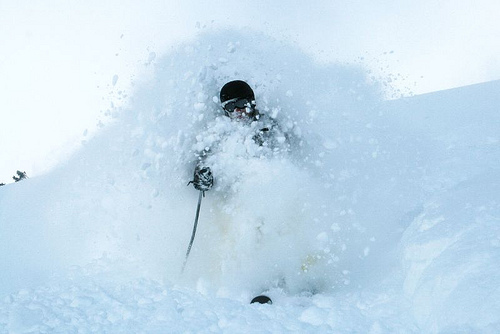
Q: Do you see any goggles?
A: Yes, there are goggles.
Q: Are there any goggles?
A: Yes, there are goggles.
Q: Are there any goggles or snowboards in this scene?
A: Yes, there are goggles.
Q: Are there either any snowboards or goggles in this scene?
A: Yes, there are goggles.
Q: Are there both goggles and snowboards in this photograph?
A: No, there are goggles but no snowboards.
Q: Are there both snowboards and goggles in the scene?
A: No, there are goggles but no snowboards.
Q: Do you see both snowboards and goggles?
A: No, there are goggles but no snowboards.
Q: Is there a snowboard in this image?
A: No, there are no snowboards.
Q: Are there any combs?
A: No, there are no combs.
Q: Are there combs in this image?
A: No, there are no combs.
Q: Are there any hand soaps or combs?
A: No, there are no combs or hand soaps.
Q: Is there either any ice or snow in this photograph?
A: Yes, there is snow.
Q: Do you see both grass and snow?
A: No, there is snow but no grass.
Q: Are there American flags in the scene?
A: No, there are no American flags.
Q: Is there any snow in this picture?
A: Yes, there is snow.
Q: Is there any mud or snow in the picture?
A: Yes, there is snow.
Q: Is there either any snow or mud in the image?
A: Yes, there is snow.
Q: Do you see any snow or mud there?
A: Yes, there is snow.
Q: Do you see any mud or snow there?
A: Yes, there is snow.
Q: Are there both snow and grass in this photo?
A: No, there is snow but no grass.